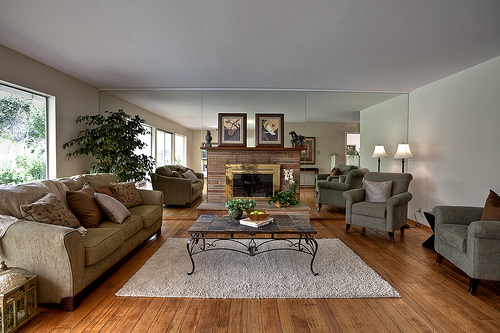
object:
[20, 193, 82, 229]
pillow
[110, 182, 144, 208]
pillow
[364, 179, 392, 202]
pillow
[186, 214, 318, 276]
table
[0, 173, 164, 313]
sofa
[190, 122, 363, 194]
wall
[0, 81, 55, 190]
window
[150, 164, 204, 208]
sofa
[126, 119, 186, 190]
window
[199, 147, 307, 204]
fireplace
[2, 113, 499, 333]
furniture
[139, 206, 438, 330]
floor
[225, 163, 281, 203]
fire place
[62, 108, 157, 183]
tree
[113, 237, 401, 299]
rug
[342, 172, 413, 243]
chair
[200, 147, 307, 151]
mantel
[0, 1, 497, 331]
room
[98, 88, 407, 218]
mirrors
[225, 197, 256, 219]
plant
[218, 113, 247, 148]
painting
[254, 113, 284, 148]
painting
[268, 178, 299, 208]
plant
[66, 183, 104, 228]
pillow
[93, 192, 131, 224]
pillow